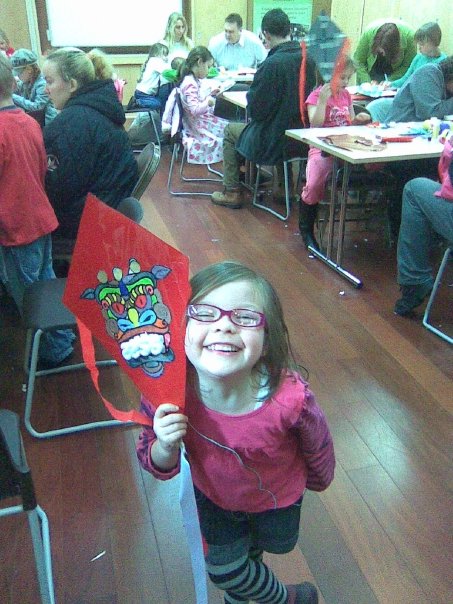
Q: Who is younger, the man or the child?
A: The child is younger than the man.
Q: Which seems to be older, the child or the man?
A: The man is older than the child.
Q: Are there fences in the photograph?
A: No, there are no fences.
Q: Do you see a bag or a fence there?
A: No, there are no fences or bags.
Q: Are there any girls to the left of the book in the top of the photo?
A: Yes, there is a girl to the left of the book.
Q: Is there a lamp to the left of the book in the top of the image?
A: No, there is a girl to the left of the book.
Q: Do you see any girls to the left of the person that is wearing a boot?
A: Yes, there is a girl to the left of the person.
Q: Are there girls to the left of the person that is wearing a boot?
A: Yes, there is a girl to the left of the person.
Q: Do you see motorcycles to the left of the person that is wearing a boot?
A: No, there is a girl to the left of the person.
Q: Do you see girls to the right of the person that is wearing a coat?
A: Yes, there is a girl to the right of the person.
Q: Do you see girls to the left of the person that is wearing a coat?
A: No, the girl is to the right of the person.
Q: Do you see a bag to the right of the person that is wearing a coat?
A: No, there is a girl to the right of the person.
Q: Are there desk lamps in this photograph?
A: No, there are no desk lamps.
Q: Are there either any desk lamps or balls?
A: No, there are no desk lamps or balls.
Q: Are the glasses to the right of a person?
A: Yes, the glasses are to the right of a person.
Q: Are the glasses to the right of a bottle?
A: No, the glasses are to the right of a person.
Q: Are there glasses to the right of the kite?
A: Yes, there are glasses to the right of the kite.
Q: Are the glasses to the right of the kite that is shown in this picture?
A: Yes, the glasses are to the right of the kite.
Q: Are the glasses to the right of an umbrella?
A: No, the glasses are to the right of the kite.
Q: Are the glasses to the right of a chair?
A: Yes, the glasses are to the right of a chair.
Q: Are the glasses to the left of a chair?
A: No, the glasses are to the right of a chair.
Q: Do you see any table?
A: Yes, there is a table.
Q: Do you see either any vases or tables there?
A: Yes, there is a table.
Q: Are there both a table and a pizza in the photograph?
A: No, there is a table but no pizzas.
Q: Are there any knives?
A: No, there are no knives.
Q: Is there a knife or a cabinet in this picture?
A: No, there are no knives or cabinets.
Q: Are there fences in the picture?
A: No, there are no fences.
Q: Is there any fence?
A: No, there are no fences.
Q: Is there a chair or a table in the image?
A: Yes, there is a chair.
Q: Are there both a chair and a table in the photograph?
A: Yes, there are both a chair and a table.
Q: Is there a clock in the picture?
A: No, there are no clocks.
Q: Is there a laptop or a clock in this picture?
A: No, there are no clocks or laptops.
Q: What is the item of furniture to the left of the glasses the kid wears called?
A: The piece of furniture is a chair.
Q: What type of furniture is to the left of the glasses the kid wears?
A: The piece of furniture is a chair.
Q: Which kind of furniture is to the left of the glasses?
A: The piece of furniture is a chair.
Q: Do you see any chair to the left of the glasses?
A: Yes, there is a chair to the left of the glasses.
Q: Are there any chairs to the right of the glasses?
A: No, the chair is to the left of the glasses.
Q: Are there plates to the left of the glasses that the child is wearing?
A: No, there is a chair to the left of the glasses.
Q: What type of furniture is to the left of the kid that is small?
A: The piece of furniture is a chair.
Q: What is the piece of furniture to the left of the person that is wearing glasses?
A: The piece of furniture is a chair.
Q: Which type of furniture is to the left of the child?
A: The piece of furniture is a chair.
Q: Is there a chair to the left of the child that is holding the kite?
A: Yes, there is a chair to the left of the kid.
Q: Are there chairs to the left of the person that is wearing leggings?
A: Yes, there is a chair to the left of the kid.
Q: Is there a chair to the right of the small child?
A: No, the chair is to the left of the kid.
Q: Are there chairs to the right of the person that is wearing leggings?
A: No, the chair is to the left of the kid.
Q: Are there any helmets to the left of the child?
A: No, there is a chair to the left of the child.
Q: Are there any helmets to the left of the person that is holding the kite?
A: No, there is a chair to the left of the child.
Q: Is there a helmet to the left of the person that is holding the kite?
A: No, there is a chair to the left of the child.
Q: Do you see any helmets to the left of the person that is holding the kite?
A: No, there is a chair to the left of the child.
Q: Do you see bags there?
A: No, there are no bags.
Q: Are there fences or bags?
A: No, there are no bags or fences.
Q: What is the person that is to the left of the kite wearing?
A: The person is wearing a shirt.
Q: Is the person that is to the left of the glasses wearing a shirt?
A: Yes, the person is wearing a shirt.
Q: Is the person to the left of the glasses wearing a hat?
A: No, the person is wearing a shirt.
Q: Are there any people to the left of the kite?
A: Yes, there is a person to the left of the kite.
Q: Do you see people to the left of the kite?
A: Yes, there is a person to the left of the kite.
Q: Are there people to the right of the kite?
A: No, the person is to the left of the kite.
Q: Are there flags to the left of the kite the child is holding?
A: No, there is a person to the left of the kite.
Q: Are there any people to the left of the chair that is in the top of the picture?
A: Yes, there is a person to the left of the chair.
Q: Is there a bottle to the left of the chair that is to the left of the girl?
A: No, there is a person to the left of the chair.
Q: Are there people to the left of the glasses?
A: Yes, there is a person to the left of the glasses.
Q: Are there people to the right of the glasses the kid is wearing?
A: No, the person is to the left of the glasses.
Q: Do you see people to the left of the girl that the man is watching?
A: Yes, there is a person to the left of the girl.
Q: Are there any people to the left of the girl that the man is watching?
A: Yes, there is a person to the left of the girl.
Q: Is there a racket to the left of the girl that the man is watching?
A: No, there is a person to the left of the girl.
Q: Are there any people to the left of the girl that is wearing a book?
A: Yes, there is a person to the left of the girl.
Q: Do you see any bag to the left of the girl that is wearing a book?
A: No, there is a person to the left of the girl.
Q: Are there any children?
A: Yes, there is a child.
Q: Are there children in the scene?
A: Yes, there is a child.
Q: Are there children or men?
A: Yes, there is a child.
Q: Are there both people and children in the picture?
A: Yes, there are both a child and a person.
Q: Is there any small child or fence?
A: Yes, there is a small child.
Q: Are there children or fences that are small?
A: Yes, the child is small.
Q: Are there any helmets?
A: No, there are no helmets.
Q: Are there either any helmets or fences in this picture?
A: No, there are no helmets or fences.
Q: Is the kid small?
A: Yes, the kid is small.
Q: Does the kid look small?
A: Yes, the kid is small.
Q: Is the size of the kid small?
A: Yes, the kid is small.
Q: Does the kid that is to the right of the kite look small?
A: Yes, the child is small.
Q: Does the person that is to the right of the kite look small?
A: Yes, the child is small.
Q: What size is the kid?
A: The kid is small.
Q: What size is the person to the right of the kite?
A: The kid is small.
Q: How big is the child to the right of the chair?
A: The kid is small.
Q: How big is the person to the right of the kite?
A: The kid is small.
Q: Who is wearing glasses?
A: The kid is wearing glasses.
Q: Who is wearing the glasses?
A: The kid is wearing glasses.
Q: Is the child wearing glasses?
A: Yes, the child is wearing glasses.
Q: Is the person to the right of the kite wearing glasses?
A: Yes, the child is wearing glasses.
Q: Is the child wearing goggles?
A: No, the child is wearing glasses.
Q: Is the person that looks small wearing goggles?
A: No, the child is wearing glasses.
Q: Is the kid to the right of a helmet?
A: No, the kid is to the right of the chair.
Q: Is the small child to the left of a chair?
A: No, the child is to the right of a chair.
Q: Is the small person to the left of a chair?
A: No, the child is to the right of a chair.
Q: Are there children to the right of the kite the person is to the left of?
A: Yes, there is a child to the right of the kite.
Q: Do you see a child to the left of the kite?
A: No, the child is to the right of the kite.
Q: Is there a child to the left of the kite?
A: No, the child is to the right of the kite.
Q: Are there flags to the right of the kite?
A: No, there is a child to the right of the kite.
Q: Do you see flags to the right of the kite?
A: No, there is a child to the right of the kite.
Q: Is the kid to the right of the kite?
A: Yes, the kid is to the right of the kite.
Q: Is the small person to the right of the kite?
A: Yes, the kid is to the right of the kite.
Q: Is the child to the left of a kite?
A: No, the child is to the right of a kite.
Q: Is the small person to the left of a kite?
A: No, the child is to the right of a kite.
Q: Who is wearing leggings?
A: The kid is wearing leggings.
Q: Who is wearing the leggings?
A: The kid is wearing leggings.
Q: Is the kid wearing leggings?
A: Yes, the kid is wearing leggings.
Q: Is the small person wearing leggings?
A: Yes, the kid is wearing leggings.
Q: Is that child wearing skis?
A: No, the child is wearing leggings.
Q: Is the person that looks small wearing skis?
A: No, the child is wearing leggings.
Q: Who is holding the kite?
A: The child is holding the kite.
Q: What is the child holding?
A: The child is holding the kite.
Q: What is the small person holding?
A: The child is holding the kite.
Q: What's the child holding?
A: The child is holding the kite.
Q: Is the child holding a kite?
A: Yes, the child is holding a kite.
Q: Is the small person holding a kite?
A: Yes, the child is holding a kite.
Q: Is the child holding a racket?
A: No, the child is holding a kite.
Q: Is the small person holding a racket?
A: No, the child is holding a kite.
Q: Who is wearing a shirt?
A: The kid is wearing a shirt.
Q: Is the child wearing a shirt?
A: Yes, the child is wearing a shirt.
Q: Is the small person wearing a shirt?
A: Yes, the child is wearing a shirt.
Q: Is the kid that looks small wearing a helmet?
A: No, the child is wearing a shirt.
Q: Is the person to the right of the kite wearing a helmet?
A: No, the child is wearing a shirt.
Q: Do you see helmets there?
A: No, there are no helmets.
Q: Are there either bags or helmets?
A: No, there are no helmets or bags.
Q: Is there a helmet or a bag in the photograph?
A: No, there are no helmets or bags.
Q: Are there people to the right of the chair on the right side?
A: Yes, there is a person to the right of the chair.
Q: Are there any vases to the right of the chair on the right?
A: No, there is a person to the right of the chair.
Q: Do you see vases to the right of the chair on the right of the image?
A: No, there is a person to the right of the chair.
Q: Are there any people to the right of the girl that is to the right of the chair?
A: Yes, there is a person to the right of the girl.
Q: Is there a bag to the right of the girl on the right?
A: No, there is a person to the right of the girl.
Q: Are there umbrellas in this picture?
A: No, there are no umbrellas.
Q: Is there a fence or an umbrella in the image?
A: No, there are no umbrellas or fences.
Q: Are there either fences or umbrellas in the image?
A: No, there are no umbrellas or fences.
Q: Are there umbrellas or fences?
A: No, there are no umbrellas or fences.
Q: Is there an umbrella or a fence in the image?
A: No, there are no umbrellas or fences.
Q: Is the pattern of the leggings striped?
A: Yes, the leggings are striped.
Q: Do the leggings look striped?
A: Yes, the leggings are striped.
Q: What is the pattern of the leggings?
A: The leggings are striped.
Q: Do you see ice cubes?
A: No, there are no ice cubes.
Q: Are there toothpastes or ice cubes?
A: No, there are no ice cubes or toothpastes.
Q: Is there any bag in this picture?
A: No, there are no bags.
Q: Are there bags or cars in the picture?
A: No, there are no bags or cars.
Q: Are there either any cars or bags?
A: No, there are no bags or cars.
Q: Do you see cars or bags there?
A: No, there are no bags or cars.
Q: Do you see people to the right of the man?
A: Yes, there is a person to the right of the man.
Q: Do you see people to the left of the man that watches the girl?
A: No, the person is to the right of the man.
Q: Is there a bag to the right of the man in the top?
A: No, there is a person to the right of the man.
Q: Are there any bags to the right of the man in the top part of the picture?
A: No, there is a person to the right of the man.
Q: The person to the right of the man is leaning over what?
A: The person is leaning over the table.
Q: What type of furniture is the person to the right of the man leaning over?
A: The person is leaning over the table.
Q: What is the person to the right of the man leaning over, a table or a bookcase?
A: The person is leaning over a table.